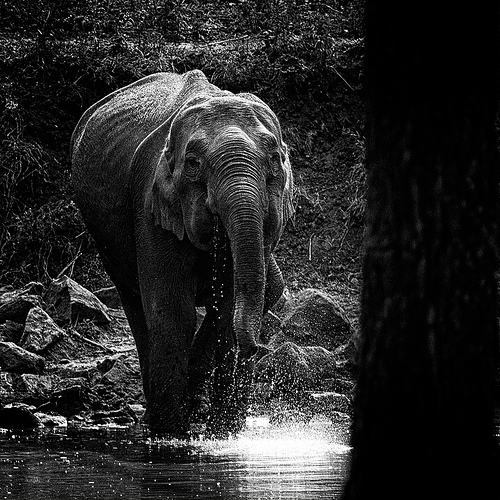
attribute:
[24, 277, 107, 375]
rock — big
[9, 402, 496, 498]
water — clear